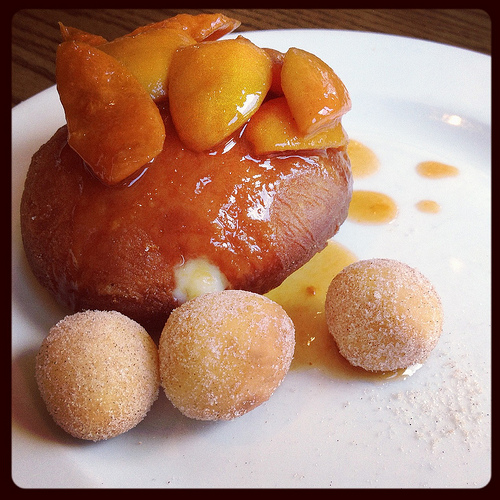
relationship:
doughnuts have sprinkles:
[31, 259, 448, 447] [111, 352, 138, 395]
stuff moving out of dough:
[172, 255, 227, 306] [21, 97, 350, 312]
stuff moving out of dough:
[179, 267, 222, 301] [21, 97, 350, 312]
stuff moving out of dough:
[172, 255, 227, 306] [135, 234, 352, 422]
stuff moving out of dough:
[172, 255, 227, 306] [47, 185, 299, 310]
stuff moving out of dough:
[172, 255, 227, 306] [53, 185, 279, 297]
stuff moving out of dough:
[172, 255, 227, 306] [316, 227, 440, 366]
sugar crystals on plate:
[137, 329, 489, 489] [11, 25, 492, 488]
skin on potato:
[277, 196, 327, 243] [38, 164, 325, 263]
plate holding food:
[375, 42, 462, 138] [64, 47, 353, 313]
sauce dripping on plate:
[339, 147, 429, 242] [368, 53, 488, 251]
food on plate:
[30, 303, 162, 454] [11, 25, 492, 488]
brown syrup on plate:
[65, 100, 306, 227] [356, 67, 486, 202]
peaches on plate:
[52, 13, 354, 187] [361, 70, 485, 253]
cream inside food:
[183, 265, 221, 295] [20, 14, 445, 444]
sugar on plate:
[389, 378, 486, 446] [11, 25, 492, 488]